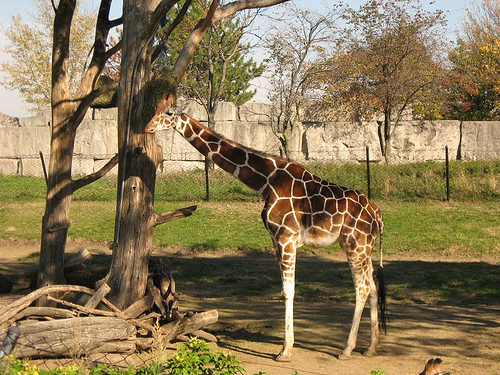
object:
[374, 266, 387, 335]
hairs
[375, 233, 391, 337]
tail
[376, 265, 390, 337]
fringes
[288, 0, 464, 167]
tree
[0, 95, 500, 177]
concrete wall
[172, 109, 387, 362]
torso neck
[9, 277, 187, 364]
wooden logs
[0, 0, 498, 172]
forest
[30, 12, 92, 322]
trunk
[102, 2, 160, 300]
trunk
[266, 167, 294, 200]
polygon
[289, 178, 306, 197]
polygon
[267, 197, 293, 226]
polygon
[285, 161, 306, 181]
polygon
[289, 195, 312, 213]
polygon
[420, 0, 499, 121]
trees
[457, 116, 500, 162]
rocks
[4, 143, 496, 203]
fence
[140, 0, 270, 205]
tree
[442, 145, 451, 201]
post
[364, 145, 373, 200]
post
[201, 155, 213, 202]
post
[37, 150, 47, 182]
post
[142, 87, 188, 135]
head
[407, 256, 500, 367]
shadow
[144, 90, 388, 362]
giraffe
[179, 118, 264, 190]
neck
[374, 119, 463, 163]
stone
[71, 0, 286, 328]
tree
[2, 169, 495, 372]
ground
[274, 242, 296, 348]
leg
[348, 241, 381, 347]
leg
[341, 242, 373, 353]
leg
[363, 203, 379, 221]
spots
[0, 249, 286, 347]
shadows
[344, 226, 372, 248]
spots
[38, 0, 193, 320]
trees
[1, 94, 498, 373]
giraffe sanctuary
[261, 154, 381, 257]
torso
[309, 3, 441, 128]
foilage